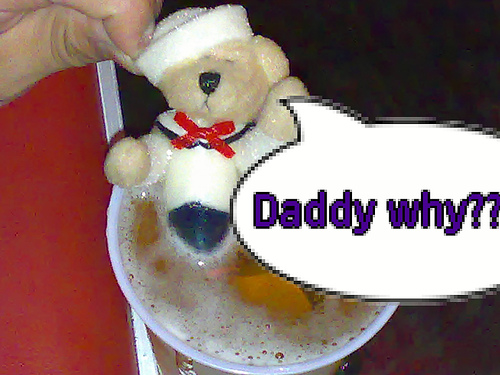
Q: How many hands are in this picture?
A: One.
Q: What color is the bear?
A: Tan.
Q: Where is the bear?
A: In the liquid.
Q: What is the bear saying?
A: Daddy why.